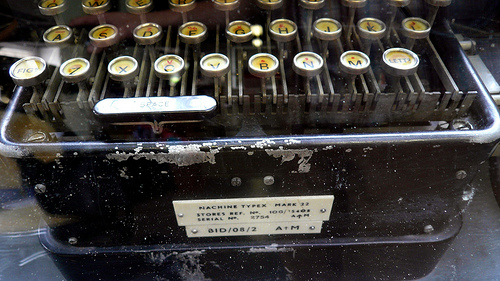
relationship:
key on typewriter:
[380, 45, 420, 80] [8, 7, 499, 279]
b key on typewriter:
[247, 53, 279, 78] [8, 7, 499, 279]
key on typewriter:
[60, 57, 87, 73] [2, 2, 497, 249]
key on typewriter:
[5, 51, 50, 86] [8, 7, 499, 279]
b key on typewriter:
[247, 52, 280, 77] [1, 0, 497, 164]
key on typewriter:
[43, 24, 73, 49] [2, 2, 497, 249]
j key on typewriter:
[310, 15, 344, 44] [8, 7, 499, 279]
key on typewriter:
[338, 50, 371, 75] [8, 7, 499, 279]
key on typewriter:
[149, 45, 208, 92] [26, 17, 472, 179]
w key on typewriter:
[83, 0, 109, 15] [8, 7, 499, 279]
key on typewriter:
[42, 25, 72, 45] [8, 7, 499, 279]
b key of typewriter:
[247, 53, 279, 78] [8, 7, 499, 279]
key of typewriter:
[339, 47, 374, 69] [8, 7, 499, 279]